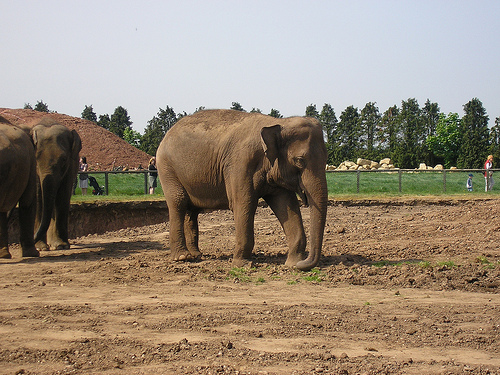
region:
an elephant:
[153, 113, 331, 263]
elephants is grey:
[156, 115, 333, 264]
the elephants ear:
[257, 127, 285, 159]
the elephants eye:
[289, 150, 306, 167]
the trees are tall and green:
[362, 106, 479, 151]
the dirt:
[106, 283, 497, 373]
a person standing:
[483, 158, 497, 189]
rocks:
[343, 155, 412, 168]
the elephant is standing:
[161, 110, 336, 261]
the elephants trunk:
[303, 189, 326, 274]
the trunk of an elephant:
[299, 173, 333, 263]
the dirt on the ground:
[34, 290, 499, 373]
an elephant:
[28, 123, 78, 250]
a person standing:
[146, 157, 159, 194]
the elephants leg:
[226, 188, 261, 264]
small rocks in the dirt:
[168, 329, 243, 363]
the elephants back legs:
[165, 191, 204, 258]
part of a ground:
[265, 288, 289, 307]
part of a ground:
[228, 276, 252, 300]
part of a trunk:
[304, 213, 335, 280]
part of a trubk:
[310, 231, 352, 302]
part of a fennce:
[421, 170, 456, 197]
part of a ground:
[312, 252, 354, 295]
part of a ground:
[241, 270, 271, 308]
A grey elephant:
[157, 102, 332, 272]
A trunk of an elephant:
[296, 175, 328, 272]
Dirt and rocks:
[0, 275, 380, 370]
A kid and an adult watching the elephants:
[458, 148, 495, 193]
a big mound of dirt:
[1, 107, 157, 172]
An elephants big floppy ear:
[256, 118, 288, 165]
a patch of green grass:
[226, 260, 267, 287]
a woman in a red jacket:
[480, 148, 495, 190]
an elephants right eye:
[292, 152, 307, 167]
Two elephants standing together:
[0, 118, 97, 265]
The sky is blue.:
[0, 1, 497, 159]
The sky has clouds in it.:
[1, 0, 498, 146]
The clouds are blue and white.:
[1, 0, 498, 150]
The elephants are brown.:
[1, 106, 328, 272]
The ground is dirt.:
[2, 200, 497, 373]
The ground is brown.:
[0, 201, 499, 373]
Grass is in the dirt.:
[223, 259, 495, 285]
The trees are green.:
[1, 100, 499, 166]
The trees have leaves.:
[0, 100, 499, 168]